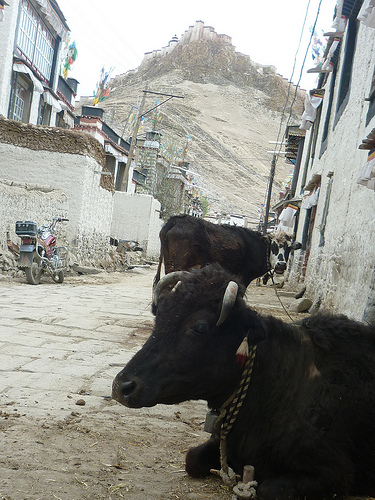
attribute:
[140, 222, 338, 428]
cattle —  two,  tied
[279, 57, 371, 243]
building — two story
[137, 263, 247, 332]
horns — cattle, turned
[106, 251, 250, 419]
head —   bull's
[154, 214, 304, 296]
bull — dark colored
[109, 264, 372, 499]
cow —  down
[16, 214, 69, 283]
motorcycle — dirty, old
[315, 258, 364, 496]
cow —  down,  cattle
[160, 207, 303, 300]
cow — black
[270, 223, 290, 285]
cow face — white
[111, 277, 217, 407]
face —   bull's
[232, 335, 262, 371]
tag — identifying